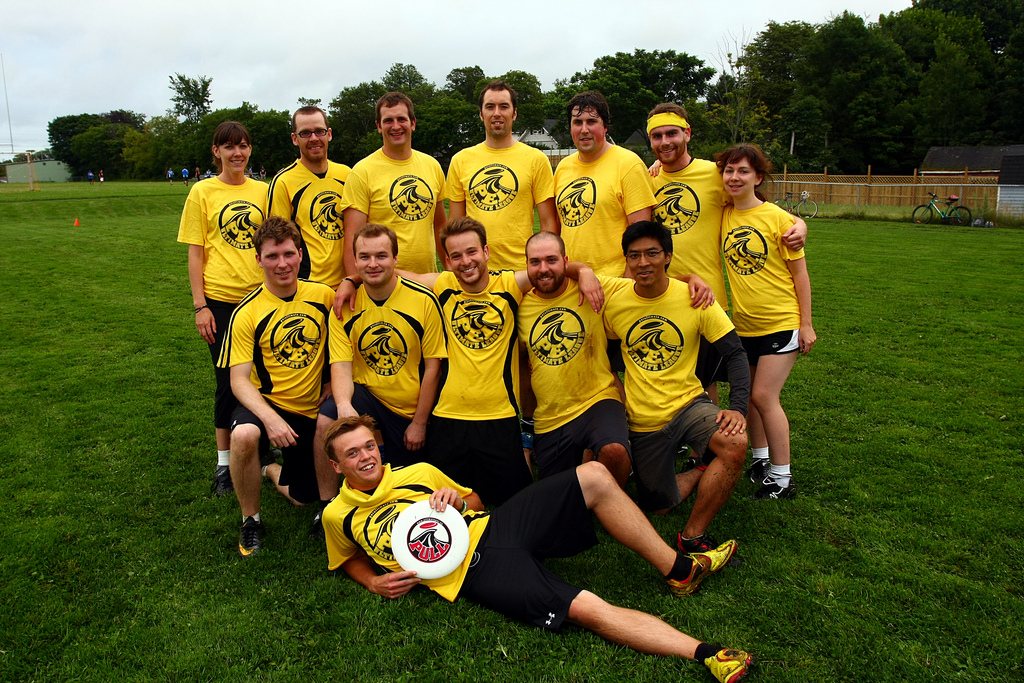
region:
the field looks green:
[768, 550, 1006, 617]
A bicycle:
[877, 170, 1007, 248]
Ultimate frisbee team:
[142, 59, 873, 671]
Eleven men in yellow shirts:
[243, 89, 721, 679]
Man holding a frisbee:
[297, 403, 811, 672]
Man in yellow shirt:
[296, 409, 824, 676]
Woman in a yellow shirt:
[702, 134, 892, 520]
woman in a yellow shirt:
[126, 115, 259, 331]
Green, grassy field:
[833, 222, 1018, 669]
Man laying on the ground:
[256, 411, 820, 678]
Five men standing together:
[262, 46, 715, 214]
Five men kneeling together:
[221, 229, 743, 356]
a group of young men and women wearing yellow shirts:
[149, 92, 861, 680]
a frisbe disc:
[384, 494, 473, 589]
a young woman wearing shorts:
[707, 136, 843, 514]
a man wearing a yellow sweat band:
[632, 95, 715, 213]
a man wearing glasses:
[268, 99, 349, 210]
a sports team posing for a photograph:
[160, 78, 805, 673]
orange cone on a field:
[56, 201, 98, 240]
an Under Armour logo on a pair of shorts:
[539, 604, 569, 637]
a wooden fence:
[824, 153, 904, 220]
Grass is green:
[49, 297, 164, 460]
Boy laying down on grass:
[314, 420, 733, 667]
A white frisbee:
[386, 472, 487, 606]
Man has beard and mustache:
[503, 217, 608, 369]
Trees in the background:
[774, 22, 980, 181]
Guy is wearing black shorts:
[325, 398, 740, 649]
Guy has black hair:
[599, 213, 698, 351]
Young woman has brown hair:
[704, 135, 801, 292]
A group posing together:
[123, 61, 842, 661]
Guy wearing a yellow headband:
[628, 96, 723, 214]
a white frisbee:
[384, 485, 479, 588]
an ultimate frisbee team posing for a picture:
[164, 90, 836, 678]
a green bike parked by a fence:
[897, 181, 986, 236]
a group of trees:
[735, 0, 1018, 157]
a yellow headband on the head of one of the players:
[638, 102, 697, 142]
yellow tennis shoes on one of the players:
[664, 523, 786, 679]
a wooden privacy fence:
[768, 156, 1003, 224]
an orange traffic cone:
[60, 204, 89, 231]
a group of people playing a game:
[82, 157, 218, 187]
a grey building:
[3, 146, 80, 189]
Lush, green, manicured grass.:
[40, 253, 162, 634]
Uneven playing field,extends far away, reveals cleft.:
[1, 139, 229, 636]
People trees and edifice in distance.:
[8, 102, 272, 204]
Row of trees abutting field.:
[68, 80, 1015, 134]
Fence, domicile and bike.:
[826, 145, 1022, 302]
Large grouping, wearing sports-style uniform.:
[178, 60, 849, 678]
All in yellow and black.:
[138, 156, 873, 635]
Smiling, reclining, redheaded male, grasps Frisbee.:
[324, 409, 737, 679]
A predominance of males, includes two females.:
[159, 92, 792, 403]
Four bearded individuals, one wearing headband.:
[285, 73, 735, 374]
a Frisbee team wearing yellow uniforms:
[166, 66, 844, 632]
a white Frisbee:
[388, 488, 477, 590]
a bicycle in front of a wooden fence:
[900, 177, 990, 232]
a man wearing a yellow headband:
[640, 91, 707, 180]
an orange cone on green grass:
[56, 203, 99, 242]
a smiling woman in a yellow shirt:
[704, 133, 802, 310]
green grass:
[27, 234, 174, 488]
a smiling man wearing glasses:
[283, 96, 359, 180]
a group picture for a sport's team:
[161, 64, 823, 494]